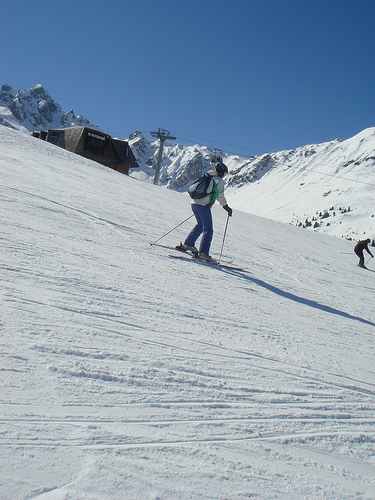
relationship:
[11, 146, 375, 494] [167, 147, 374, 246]
snow on slopes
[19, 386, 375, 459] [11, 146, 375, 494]
tracks in snow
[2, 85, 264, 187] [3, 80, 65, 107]
mountains have snow caps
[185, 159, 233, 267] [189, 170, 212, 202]
skier wears backpack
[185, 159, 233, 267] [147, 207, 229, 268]
skier has poles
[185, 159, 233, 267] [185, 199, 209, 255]
skier wears pants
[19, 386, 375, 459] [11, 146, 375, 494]
tracks on snow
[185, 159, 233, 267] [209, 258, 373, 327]
skier has shadow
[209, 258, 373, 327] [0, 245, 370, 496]
shadow on ground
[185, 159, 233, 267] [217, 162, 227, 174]
skier wears cap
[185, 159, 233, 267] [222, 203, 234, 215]
skier wears gloves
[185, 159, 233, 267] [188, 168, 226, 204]
skier wears jacket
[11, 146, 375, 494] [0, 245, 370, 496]
snow on ground